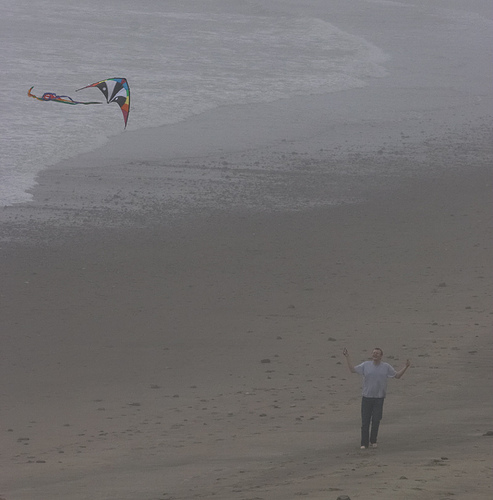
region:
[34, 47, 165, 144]
a kite in the sky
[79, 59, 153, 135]
a face on a kite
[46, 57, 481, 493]
a man flying kite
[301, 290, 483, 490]
a man on the beach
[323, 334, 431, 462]
white shirt and gray pants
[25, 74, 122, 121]
a green and red tail on kite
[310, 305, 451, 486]
man with hands in the air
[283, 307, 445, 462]
a man walking on beach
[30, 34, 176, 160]
a kite in the air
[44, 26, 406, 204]
water coming up on beach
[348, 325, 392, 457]
man standing on sandy beach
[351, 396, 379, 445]
black pants on man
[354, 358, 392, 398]
white shirt on man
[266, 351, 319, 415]
footprints on sandy beach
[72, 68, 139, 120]
kite flying over beach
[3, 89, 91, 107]
kite flying over beach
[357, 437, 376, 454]
white shoes on man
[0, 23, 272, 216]
waves crashing in on beach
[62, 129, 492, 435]
light fog over beach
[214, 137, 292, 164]
water bubbles on sand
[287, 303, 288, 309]
part of a shore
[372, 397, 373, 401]
part of a shirt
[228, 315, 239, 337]
part of the sea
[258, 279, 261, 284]
edge of a sea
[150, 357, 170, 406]
edge of a sea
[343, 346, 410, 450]
A man standing on the sand.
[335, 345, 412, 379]
The man raising his arms.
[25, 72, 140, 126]
The colorful kite in the air.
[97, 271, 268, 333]
The grey sandy beach.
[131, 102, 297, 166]
The grey sandy shoreline.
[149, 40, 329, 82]
The clear looking water.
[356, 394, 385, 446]
The man's dark-colored pants.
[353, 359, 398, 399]
The man's white tee shirt.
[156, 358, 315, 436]
The disturbed sand on the beach.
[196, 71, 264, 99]
Ripples in the clear water.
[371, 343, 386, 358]
head of a person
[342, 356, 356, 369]
arm of a person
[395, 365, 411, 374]
arm of a person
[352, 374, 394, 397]
body of a person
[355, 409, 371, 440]
leg of a person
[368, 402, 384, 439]
leg of a person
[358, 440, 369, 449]
feet of a person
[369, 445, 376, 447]
feet of a person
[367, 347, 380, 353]
eye of a person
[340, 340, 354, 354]
hand of a person